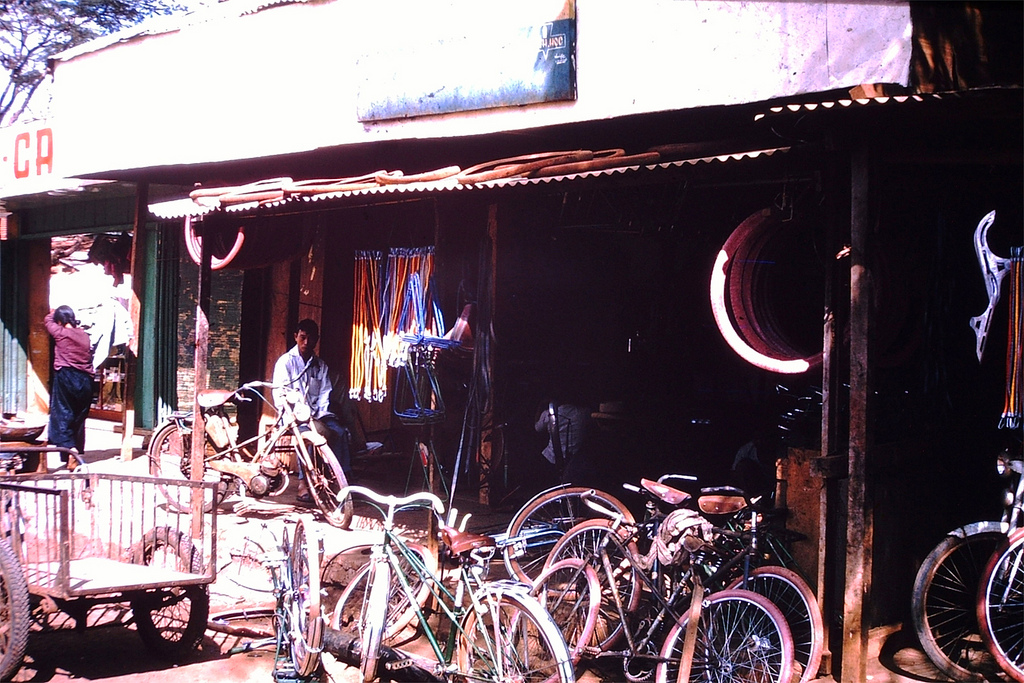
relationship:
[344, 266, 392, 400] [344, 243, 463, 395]
curtain hanging in front of window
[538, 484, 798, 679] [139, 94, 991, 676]
bicycle standing in front of bike shop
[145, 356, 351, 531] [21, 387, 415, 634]
bike on sidewalk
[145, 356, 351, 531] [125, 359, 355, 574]
bike on sidewalk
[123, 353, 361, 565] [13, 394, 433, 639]
bike on sidewalk